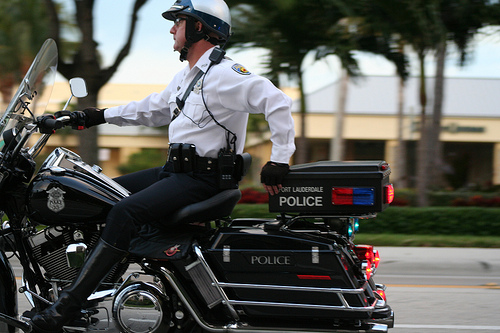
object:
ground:
[354, 243, 499, 330]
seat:
[170, 189, 242, 223]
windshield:
[0, 36, 60, 140]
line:
[387, 283, 499, 290]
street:
[363, 243, 498, 325]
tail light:
[382, 182, 394, 204]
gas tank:
[23, 146, 134, 227]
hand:
[83, 107, 107, 130]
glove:
[80, 107, 107, 129]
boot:
[29, 236, 127, 331]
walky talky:
[218, 149, 236, 187]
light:
[355, 245, 380, 281]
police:
[277, 186, 375, 207]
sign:
[409, 119, 484, 133]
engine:
[30, 232, 88, 290]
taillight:
[353, 244, 380, 281]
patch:
[231, 62, 252, 75]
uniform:
[101, 44, 298, 252]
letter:
[279, 197, 287, 206]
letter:
[287, 196, 296, 207]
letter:
[296, 197, 304, 207]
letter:
[306, 196, 315, 207]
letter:
[315, 196, 323, 206]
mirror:
[69, 77, 88, 98]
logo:
[46, 186, 66, 212]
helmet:
[160, 1, 231, 44]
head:
[169, 0, 232, 54]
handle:
[70, 111, 87, 130]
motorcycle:
[1, 37, 400, 333]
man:
[30, 0, 299, 329]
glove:
[260, 161, 291, 186]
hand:
[260, 161, 290, 196]